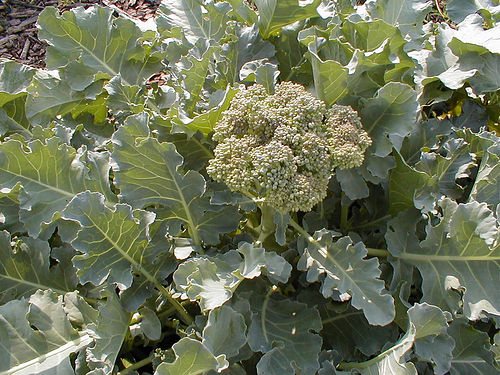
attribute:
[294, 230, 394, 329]
leaf — large, green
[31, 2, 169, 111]
leaf — green, large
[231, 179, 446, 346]
leaf — green, large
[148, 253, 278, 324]
leaf — green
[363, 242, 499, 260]
stem — thick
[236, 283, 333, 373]
leaf — large, green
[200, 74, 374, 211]
broccoli — strong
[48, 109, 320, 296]
leaf — green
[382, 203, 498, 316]
green leaf — large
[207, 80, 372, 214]
cauliflower — large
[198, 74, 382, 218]
broccoli — full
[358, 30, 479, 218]
leaves — surrounding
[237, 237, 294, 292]
leaf — green, large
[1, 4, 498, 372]
plant — white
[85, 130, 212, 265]
leaf — large, green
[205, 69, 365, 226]
broccoli — lime green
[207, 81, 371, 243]
brocolli —  bunch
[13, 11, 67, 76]
sticks — brown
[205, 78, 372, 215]
plant — white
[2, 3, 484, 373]
leaves —  wrinkled, large